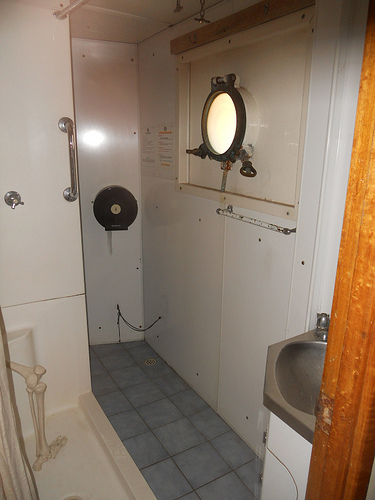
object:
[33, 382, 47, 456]
skeleton`s leg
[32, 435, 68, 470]
foot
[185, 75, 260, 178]
frame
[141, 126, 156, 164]
sign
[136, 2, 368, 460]
wall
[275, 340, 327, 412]
sink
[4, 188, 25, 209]
tap valve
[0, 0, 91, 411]
wall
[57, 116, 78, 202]
handle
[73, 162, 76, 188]
metal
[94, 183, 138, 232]
dispenser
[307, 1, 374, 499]
door frame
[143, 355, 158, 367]
drain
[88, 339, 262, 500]
ground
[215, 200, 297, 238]
towel bar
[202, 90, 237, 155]
port hole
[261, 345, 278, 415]
sink edge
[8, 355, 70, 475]
skeleton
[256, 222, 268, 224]
paint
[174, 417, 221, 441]
grout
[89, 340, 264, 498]
floor